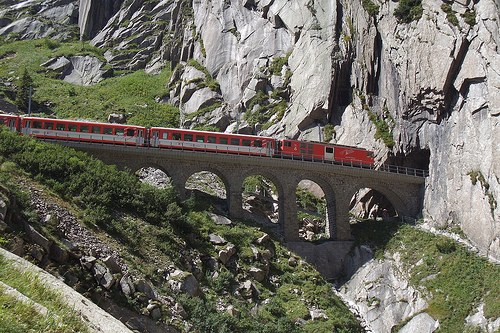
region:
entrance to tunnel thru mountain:
[379, 140, 441, 184]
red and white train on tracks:
[3, 108, 388, 175]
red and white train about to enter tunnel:
[3, 98, 443, 180]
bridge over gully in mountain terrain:
[91, 150, 447, 253]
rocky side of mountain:
[182, 0, 495, 115]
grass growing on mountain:
[47, 65, 176, 109]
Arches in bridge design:
[131, 155, 411, 260]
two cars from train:
[18, 110, 278, 164]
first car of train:
[279, 137, 376, 167]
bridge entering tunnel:
[378, 134, 450, 240]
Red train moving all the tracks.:
[2, 100, 382, 175]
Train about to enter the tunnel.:
[10, 99, 450, 185]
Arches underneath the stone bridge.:
[118, 151, 428, 258]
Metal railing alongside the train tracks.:
[376, 157, 431, 184]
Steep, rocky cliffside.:
[178, 0, 496, 121]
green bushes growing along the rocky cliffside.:
[12, 135, 222, 266]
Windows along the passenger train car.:
[164, 127, 269, 151]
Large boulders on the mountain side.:
[155, 229, 307, 301]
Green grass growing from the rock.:
[1, 233, 95, 331]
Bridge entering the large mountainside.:
[377, 140, 445, 220]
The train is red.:
[7, 90, 387, 184]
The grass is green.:
[36, 55, 233, 145]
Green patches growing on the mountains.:
[84, 10, 337, 124]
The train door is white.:
[318, 134, 335, 164]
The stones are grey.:
[406, 55, 489, 246]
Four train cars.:
[7, 103, 413, 239]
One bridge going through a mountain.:
[46, 101, 428, 261]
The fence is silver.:
[105, 115, 423, 177]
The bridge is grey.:
[105, 148, 420, 233]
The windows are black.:
[162, 113, 271, 158]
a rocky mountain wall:
[131, 4, 498, 126]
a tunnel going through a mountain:
[342, 120, 464, 260]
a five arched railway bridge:
[108, 149, 458, 249]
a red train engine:
[278, 107, 386, 169]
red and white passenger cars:
[11, 106, 277, 158]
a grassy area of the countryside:
[391, 219, 495, 325]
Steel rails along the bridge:
[377, 160, 438, 185]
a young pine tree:
[4, 49, 52, 108]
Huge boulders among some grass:
[156, 222, 288, 317]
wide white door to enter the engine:
[316, 142, 342, 163]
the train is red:
[75, 121, 348, 163]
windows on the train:
[38, 120, 128, 136]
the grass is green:
[37, 144, 147, 209]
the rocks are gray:
[417, 73, 487, 231]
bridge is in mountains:
[136, 144, 471, 316]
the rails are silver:
[149, 137, 293, 158]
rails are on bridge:
[81, 131, 336, 163]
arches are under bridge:
[141, 142, 370, 241]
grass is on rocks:
[12, 207, 255, 317]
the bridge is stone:
[162, 154, 348, 202]